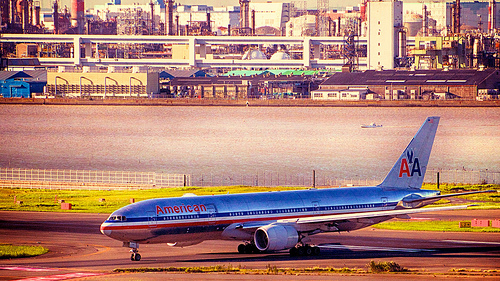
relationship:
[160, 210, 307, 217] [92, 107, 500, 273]
windows on airplane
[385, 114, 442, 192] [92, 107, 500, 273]
tail on airplane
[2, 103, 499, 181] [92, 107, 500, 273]
water next to airplane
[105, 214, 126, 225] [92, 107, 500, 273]
windsheild on front plane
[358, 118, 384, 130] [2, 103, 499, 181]
boat in water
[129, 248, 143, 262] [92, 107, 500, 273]
wheel on airplane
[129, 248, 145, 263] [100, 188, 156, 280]
wheels are on front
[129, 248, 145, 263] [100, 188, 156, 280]
wheel on front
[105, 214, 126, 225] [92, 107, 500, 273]
windsheild of a plane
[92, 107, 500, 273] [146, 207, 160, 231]
airplane has a door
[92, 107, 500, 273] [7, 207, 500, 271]
plane on runway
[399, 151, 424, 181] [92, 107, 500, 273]
logo of american airlines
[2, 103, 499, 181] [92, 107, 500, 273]
water behind plane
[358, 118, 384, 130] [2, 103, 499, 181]
boat on water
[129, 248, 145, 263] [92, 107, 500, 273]
front wheel f plane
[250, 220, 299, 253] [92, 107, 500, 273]
engine of plane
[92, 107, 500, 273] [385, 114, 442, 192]
airplane has tail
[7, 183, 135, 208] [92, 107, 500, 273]
green grass by airplane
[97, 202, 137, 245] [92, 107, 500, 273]
nose of airplane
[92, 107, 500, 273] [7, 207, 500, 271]
plane in run way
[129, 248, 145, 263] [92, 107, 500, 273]
wheel of a plane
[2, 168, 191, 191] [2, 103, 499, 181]
fence next to river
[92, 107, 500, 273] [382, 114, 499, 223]
plane seen back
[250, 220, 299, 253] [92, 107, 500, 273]
engine of airplane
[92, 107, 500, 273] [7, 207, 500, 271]
airplane on runway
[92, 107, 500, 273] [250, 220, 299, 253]
airplane has an engine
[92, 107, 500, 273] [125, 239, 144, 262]
airplane has landing gear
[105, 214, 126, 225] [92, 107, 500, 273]
windsheild of an airplane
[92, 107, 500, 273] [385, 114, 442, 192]
airplane seen tail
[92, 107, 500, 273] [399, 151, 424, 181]
airplane has a logo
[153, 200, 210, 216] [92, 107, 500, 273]
letter painted on airplane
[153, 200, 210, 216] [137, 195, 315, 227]
letter painted on side